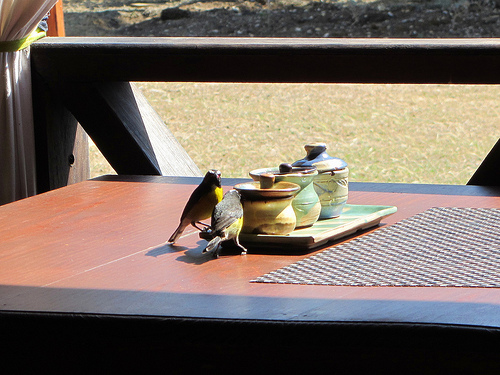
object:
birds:
[199, 188, 248, 258]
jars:
[233, 173, 301, 234]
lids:
[265, 163, 318, 175]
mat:
[248, 206, 500, 289]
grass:
[204, 88, 461, 177]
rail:
[154, 37, 437, 83]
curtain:
[2, 0, 51, 203]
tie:
[0, 29, 40, 54]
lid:
[292, 142, 347, 171]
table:
[0, 175, 500, 351]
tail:
[200, 232, 226, 255]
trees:
[158, 10, 495, 37]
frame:
[47, 5, 65, 39]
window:
[25, 0, 500, 187]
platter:
[200, 203, 397, 248]